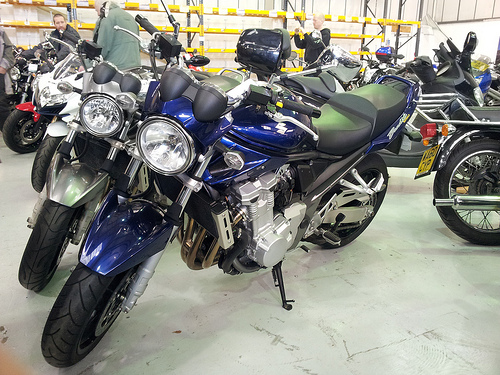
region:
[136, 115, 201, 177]
head lamp of bike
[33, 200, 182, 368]
Front wheel of bike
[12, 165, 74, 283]
Tire of a bike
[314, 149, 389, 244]
Back wheel of bike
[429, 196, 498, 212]
Exhaust of a bike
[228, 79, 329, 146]
Left handle bar of bike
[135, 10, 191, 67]
Right handle bar of bike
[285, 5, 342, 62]
A man taking a picture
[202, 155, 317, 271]
The motor of bike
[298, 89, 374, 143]
The seat of bike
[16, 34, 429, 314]
line of motorcycles together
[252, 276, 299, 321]
black kickstand to motorcycle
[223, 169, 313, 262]
silver engine of motorcycle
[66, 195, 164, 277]
blue front wheel of motorcycle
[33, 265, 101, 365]
black front wheel of motorycle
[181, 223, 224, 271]
silver tubes on motorcycle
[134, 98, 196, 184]
front light of motorcycle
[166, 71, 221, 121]
black lights on motorcycle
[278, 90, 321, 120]
black handle bars on motorcycle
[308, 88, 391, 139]
black seat on back of cycle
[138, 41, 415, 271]
motorcycle sitting in warehouse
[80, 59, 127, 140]
motorcycle sitting in warehouse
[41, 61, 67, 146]
motorcycle sitting in warehouse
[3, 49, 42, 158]
motorcycle sitting in warehouse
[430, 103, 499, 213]
motorcycle sitting in warehouse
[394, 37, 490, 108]
motorcycle sitting in warehouse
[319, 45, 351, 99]
motorcycle sitting in warehouse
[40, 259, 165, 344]
black rubber tire of motorcycle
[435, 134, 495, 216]
black rubber tire of motorcycle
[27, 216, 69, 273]
black rubber tire of motorcycle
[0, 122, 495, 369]
flat light-gray floor with scratches and marks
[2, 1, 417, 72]
yellow and white railing by back wall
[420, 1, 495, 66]
open doorway to outside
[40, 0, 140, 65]
seated and standing man talking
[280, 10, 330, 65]
man looking at something in hands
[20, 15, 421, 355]
parked motorcycles slanted in one direction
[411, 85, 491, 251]
extended rack over lights and licence plate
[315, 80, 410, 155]
low divider between green seating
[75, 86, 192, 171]
round and shiny unlit headlights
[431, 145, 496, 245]
exhaust pipe across black wheel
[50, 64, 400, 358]
blue motorbike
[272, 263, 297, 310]
black kickstand of blue motorbike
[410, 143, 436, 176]
yellow license plate with black lettering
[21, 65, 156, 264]
silver motorbike leaning on blue motorbike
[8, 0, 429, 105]
yellow railing on the back wall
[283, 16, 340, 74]
man wearing black shirt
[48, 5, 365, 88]
people walking among the motorcycles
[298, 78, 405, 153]
black seat of the blue motorcycle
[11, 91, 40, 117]
red fender over black tire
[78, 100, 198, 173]
front headlights on blue and silver motorcycles